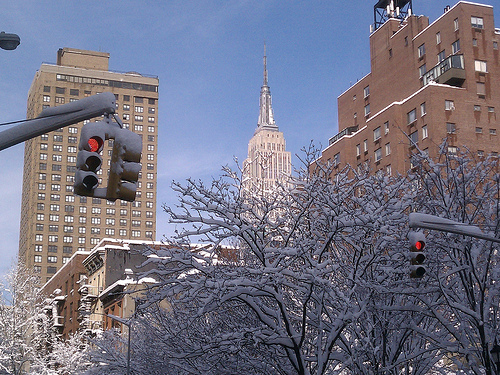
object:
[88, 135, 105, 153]
red light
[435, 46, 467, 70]
glass window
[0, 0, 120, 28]
blue sky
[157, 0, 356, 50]
blue sky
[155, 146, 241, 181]
cloud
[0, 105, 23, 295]
cloud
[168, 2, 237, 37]
cloud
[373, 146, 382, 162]
window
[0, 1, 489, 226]
sky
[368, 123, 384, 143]
window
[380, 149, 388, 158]
glass window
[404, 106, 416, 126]
window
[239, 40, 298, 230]
tower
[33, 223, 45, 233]
window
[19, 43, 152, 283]
building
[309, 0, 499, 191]
building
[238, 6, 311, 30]
white clouds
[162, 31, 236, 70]
white clouds